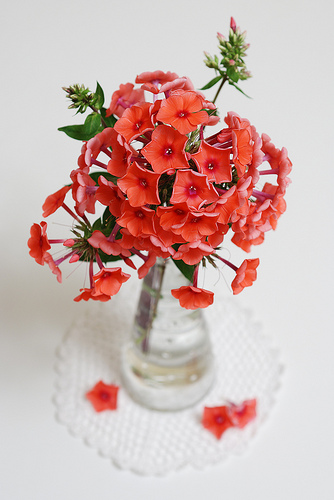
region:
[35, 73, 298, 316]
Flowers are in the foreground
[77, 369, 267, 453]
Flower pedals are on the ground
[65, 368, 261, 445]
Flower pedals on the ground are red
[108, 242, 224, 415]
Flower vase is clear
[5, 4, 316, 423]
The flower vase is filled with water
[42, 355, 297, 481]
The flower pedals are blurred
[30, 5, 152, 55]
Background is light gray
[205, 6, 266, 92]
Flower in the background are green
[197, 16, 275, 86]
Flowers in the background are in bloom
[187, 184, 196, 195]
Inside flower pedal is purple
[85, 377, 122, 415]
A flower petal on the table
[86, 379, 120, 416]
The flower is red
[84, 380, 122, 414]
The flower is shaped like a star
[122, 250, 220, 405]
A clear glass vase on a table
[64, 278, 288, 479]
A white lace doylie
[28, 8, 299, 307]
A bunch of flowers in a vase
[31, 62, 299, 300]
The flowers are small and red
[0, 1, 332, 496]
The table is white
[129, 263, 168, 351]
The green stem of the flowers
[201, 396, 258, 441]
Two more petals on the table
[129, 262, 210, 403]
Water in a vase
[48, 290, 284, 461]
A round doily under a vase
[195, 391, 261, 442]
Flowers fallen onto a white doily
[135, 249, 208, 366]
A glass vase for flowers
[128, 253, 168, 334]
Visible stems in the water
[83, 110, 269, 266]
Beautiful pink flowers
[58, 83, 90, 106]
Small flower buds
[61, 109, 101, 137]
Green leaves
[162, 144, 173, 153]
Three tiny balls in the center of a flower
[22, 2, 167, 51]
A white background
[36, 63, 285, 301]
The flowers are red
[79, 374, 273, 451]
Three flower pedals are on the ground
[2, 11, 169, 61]
The background is light gray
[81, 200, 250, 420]
Flowers are in a vase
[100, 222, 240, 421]
The vase is filled with water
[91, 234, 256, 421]
The vase is clear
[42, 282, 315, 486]
The vase is on a white circular object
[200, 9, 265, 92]
flowers are in bloom in the background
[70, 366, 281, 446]
The flower pedals are out of focus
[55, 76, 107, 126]
Flowers in the background are green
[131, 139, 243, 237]
a bundle of orange flowers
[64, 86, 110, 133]
a closed flower bud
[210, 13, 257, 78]
a flower bud beginning to blossom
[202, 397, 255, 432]
two flowers which have fallen off the bunch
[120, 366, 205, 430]
the bottom of a glass vase sitting on a doily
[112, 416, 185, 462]
a white doily on a white table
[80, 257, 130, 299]
two flowers hanging down from a bunch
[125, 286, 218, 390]
a glass vase with green stems inside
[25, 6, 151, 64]
a white table behind the vase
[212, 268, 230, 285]
long strands extending from flowers